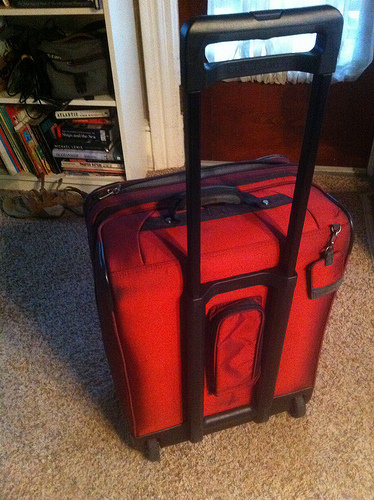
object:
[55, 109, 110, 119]
book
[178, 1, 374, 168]
door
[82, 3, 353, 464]
case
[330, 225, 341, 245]
zipper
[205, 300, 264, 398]
stain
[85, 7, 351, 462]
travel case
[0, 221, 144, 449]
shadow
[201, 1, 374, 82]
curtain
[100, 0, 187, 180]
door frame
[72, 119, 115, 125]
book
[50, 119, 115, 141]
book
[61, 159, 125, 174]
book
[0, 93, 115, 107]
shelf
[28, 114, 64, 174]
book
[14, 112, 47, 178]
book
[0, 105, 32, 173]
book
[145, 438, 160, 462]
wheel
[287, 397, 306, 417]
wheel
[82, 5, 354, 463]
luggage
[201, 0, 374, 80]
window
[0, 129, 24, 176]
bookshelf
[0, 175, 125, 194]
shelf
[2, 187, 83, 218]
sandal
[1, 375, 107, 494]
floor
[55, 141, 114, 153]
books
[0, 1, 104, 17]
shelf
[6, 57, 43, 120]
wire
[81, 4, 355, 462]
suitcase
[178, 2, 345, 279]
handle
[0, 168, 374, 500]
carpet